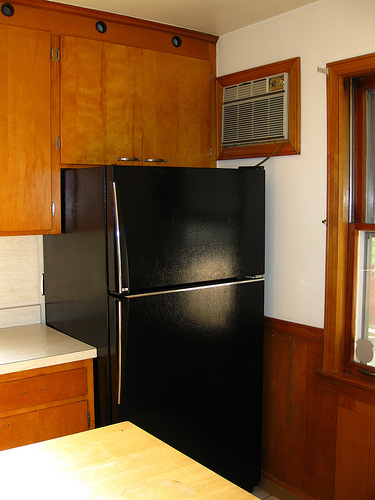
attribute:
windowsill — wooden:
[325, 77, 372, 373]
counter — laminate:
[1, 313, 97, 366]